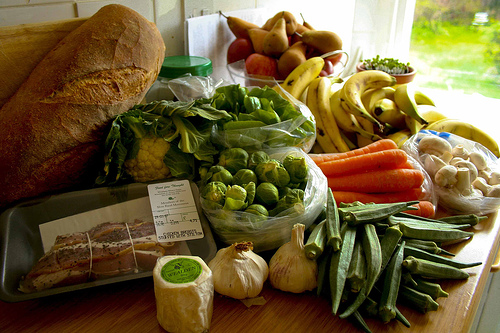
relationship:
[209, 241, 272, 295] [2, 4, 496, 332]
garlic on top of table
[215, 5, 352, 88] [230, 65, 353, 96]
pears inside bowl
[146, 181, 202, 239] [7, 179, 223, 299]
tag on package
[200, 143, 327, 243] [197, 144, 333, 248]
brussel sprouts inside bag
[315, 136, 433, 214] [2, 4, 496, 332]
carrots on top of counter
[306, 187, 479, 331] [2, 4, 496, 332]
okra on top of counter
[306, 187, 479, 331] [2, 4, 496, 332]
okra on top of building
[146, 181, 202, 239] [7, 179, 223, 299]
tag on top of product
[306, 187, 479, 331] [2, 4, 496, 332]
okra on top of a table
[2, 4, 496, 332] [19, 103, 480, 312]
food on table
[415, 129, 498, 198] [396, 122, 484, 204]
mushrooms in bag